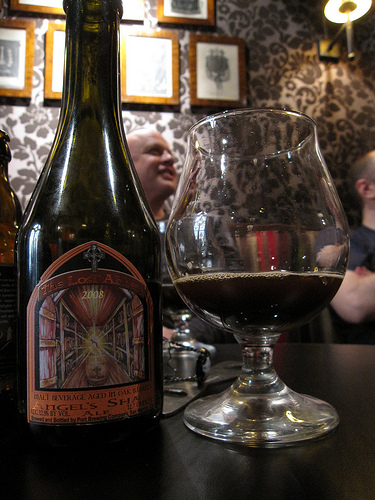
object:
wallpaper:
[0, 0, 375, 234]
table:
[0, 329, 375, 499]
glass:
[162, 102, 351, 454]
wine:
[171, 270, 343, 335]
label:
[22, 241, 157, 431]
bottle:
[12, 0, 165, 456]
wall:
[0, 0, 374, 230]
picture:
[0, 20, 35, 100]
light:
[319, 0, 375, 30]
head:
[123, 130, 178, 200]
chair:
[233, 221, 330, 345]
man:
[315, 148, 375, 350]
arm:
[316, 241, 374, 326]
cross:
[83, 243, 106, 271]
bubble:
[172, 269, 346, 283]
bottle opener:
[165, 336, 215, 397]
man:
[122, 121, 243, 342]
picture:
[115, 23, 179, 113]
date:
[81, 290, 103, 300]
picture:
[10, 0, 64, 18]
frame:
[187, 31, 249, 112]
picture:
[156, 1, 216, 30]